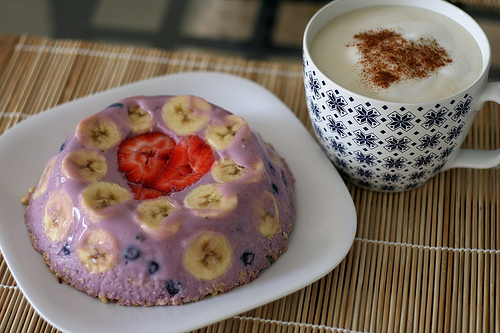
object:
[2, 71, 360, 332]
plate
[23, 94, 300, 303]
desert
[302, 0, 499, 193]
cup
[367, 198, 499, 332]
platemat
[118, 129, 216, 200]
cherry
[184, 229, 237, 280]
banana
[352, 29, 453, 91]
cinnamon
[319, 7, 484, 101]
drink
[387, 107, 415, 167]
design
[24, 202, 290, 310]
flan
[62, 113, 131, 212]
bananas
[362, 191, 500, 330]
placemat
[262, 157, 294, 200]
blueberry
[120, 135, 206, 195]
fruit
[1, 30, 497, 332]
table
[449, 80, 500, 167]
handle